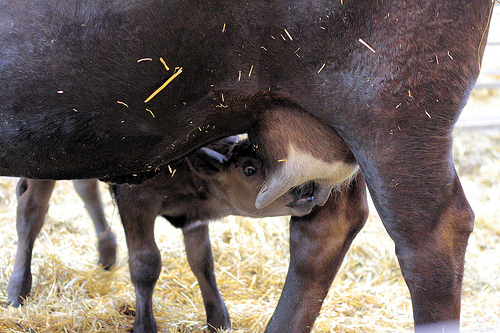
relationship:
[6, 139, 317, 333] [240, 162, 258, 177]
calf has eye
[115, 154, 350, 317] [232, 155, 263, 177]
calf has eye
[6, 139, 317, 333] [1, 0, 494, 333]
calf under mom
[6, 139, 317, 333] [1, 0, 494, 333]
calf nursing from mom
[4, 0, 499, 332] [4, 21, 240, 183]
cow has belly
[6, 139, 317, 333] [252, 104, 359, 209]
calf next to udders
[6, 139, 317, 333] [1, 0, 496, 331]
calf below mom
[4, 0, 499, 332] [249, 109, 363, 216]
cow has udders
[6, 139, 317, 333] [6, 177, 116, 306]
calf has legs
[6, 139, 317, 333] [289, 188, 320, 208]
calf has teeth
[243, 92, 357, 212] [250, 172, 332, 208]
udders has teats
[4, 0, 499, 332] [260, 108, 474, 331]
cow has feet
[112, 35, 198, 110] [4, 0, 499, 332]
hay under cow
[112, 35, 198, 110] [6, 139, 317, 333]
hay under calf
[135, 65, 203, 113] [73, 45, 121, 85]
straw on fur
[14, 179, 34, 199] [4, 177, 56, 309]
opening on leg